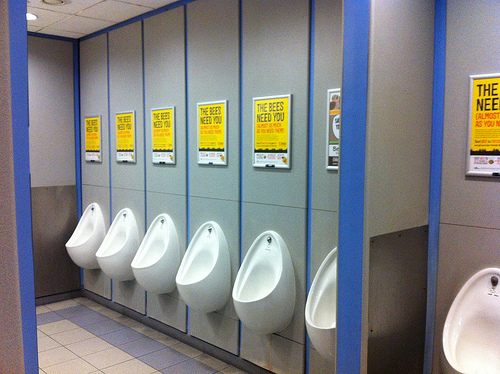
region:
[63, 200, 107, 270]
a white urinal on the wall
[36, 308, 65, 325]
a blue floor tile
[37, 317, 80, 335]
a gray floor tile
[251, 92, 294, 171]
a framed advertisement on the wall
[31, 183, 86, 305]
a silver metal wall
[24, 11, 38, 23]
a white light on the ceiling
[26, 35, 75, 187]
a gray wall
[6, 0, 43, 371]
blue trim on the wall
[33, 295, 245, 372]
a blue and gray tiled floor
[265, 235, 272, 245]
a metal bolt on the urinal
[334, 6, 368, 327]
the edge is blue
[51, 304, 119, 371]
the ground is tiled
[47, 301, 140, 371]
the floor is gray and blue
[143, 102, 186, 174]
the sign is yellow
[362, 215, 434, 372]
the panel is dark gray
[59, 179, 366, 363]
there are many urinals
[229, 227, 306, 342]
the urinal is white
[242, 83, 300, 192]
the sign says the bees need you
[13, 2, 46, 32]
the light is on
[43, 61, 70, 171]
the wall is gray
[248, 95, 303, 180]
yellow sign with black writing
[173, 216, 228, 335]
white urinal attached to wall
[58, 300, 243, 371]
row of blue tiles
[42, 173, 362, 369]
row of six urinals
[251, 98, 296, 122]
black text saying "the bees need you"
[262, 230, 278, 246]
silver knob on the urinal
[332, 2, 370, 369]
blue trim in the archway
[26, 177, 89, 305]
metal siding on the wall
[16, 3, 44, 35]
light built into the ceiling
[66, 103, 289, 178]
five identical signs on the wall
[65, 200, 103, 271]
white urinal on wall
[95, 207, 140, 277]
white urinal between two urinals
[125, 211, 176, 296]
oval shaped urinal on wall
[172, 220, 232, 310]
white urinal under sign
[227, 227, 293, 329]
white urinal on the wall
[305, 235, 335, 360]
white urinal next to urinal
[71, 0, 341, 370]
gray and blue striped wall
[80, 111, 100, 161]
yellow, white and black sign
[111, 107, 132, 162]
sign above urinal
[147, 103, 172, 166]
sign on the wall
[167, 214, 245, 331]
the urinal is white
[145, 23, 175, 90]
the wall is gray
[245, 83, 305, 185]
the poster is yellow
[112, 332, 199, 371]
the ground is gray and blue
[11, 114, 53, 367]
the edge is blue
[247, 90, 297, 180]
the poster says the bees need you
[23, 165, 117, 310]
the panel is dark gray